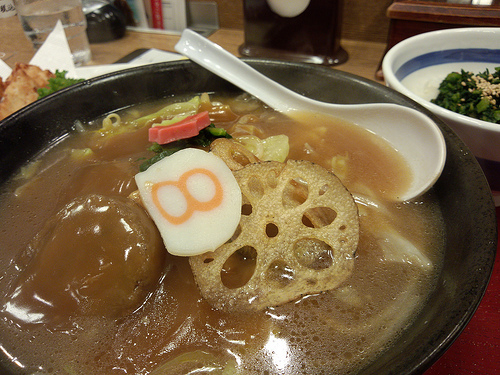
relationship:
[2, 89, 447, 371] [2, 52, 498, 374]
stew sitting in bowl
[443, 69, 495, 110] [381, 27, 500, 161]
vegetable sitting in bowl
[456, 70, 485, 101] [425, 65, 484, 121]
sauce covering vegetable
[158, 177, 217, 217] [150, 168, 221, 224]
yolk forming eight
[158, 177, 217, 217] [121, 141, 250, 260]
yolk belonging to cooked egg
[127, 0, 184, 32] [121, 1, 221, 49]
mail sitting in holder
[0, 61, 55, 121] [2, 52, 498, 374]
bread sitting next to bowl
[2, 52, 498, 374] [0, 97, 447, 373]
bowl containing soup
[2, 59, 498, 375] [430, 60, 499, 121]
bowl to cut green vegetables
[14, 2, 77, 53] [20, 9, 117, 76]
glass of water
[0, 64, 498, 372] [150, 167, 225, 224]
food in shape of an eight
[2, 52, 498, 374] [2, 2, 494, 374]
bowl on table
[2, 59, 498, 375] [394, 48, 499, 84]
bowl has a blue trim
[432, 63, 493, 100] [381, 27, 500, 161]
leaves in bowl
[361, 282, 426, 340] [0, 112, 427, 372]
noodles are in broth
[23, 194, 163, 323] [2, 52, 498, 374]
meat piece in bowl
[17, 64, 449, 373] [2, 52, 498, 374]
soup inside bowl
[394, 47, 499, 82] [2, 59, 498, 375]
ring around bowl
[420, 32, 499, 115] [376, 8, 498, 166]
salad inside white bowl